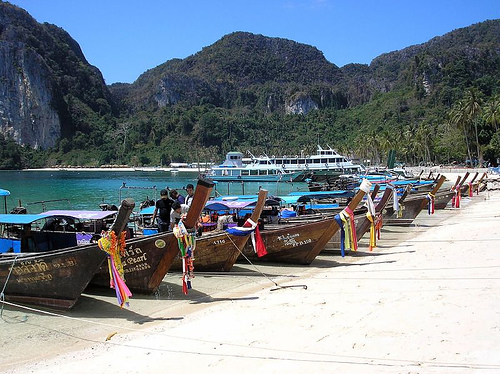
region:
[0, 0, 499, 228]
the mountains near the water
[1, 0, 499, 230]
the water near the mountains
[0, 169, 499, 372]
the sand near the water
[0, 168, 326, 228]
the body of water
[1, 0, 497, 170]
the trees on and near the mountains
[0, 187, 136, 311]
the parked boat with a blue roof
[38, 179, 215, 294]
the parked boat with a purple roof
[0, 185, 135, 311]
the fabric hanging from the parked boat with a blue roof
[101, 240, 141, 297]
decoration on a boat.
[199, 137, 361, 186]
A large ship in the water.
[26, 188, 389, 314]
A row of small boats no the shore.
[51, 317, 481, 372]
Sand on the shore of a beach.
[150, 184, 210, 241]
People standing on a boat.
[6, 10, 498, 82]
Grass covered mountain tops.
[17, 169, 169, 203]
Body of water.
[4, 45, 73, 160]
A rocky steep cliff.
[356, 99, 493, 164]
A row of tall palm trees.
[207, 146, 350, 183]
white boats in the water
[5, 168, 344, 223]
blue green ocean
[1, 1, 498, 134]
tree covered mountains behind the boats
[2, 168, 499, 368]
white sand on the beach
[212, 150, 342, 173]
cabins on the two white boats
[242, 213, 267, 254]
red and white scarf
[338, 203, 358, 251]
blue, white, and pink scaves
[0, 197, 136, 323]
boat on sandy beach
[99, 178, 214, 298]
boat on sandy beach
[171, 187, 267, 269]
boat on sandy beach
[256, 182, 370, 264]
boat on sandy beach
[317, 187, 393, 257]
boat on sandy beach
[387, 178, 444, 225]
boat on sandy beach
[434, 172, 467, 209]
boat on sandy beach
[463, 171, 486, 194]
boat on sandy beach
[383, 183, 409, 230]
boat on sandy beach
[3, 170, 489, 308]
boats on sandy beach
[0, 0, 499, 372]
A seaside area surrounded by cliffs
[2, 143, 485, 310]
Boats at a seaside location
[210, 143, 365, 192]
A white yacht at anchor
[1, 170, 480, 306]
Small wooden boats on the sand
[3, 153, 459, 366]
many boats on the beach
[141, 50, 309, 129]
many trees next to water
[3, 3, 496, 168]
tall mountains in the back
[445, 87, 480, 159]
palm tree in the back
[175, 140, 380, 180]
white boat in the water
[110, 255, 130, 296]
pink flag on the boat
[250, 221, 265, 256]
red flag on boat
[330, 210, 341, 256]
blue flag on boat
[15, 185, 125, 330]
boat docked on shore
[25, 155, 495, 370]
sand on the beach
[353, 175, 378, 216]
white flag on boat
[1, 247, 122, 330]
A boat on the beach.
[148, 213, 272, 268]
A boat on the beach.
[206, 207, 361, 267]
A boat on the beach.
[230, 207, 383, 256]
A boat on the beach.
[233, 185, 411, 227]
A boat on the beach.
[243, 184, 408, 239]
A boat on the beach.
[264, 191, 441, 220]
A boat on the beach.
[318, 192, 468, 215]
A boat on the beach.